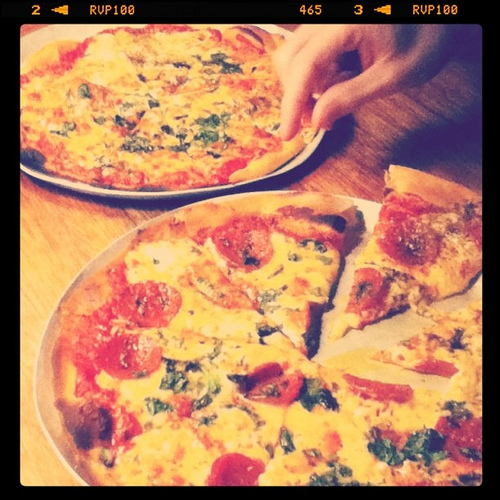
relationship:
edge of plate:
[21, 157, 143, 202] [11, 100, 330, 206]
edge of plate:
[22, 179, 251, 200] [16, 26, 333, 196]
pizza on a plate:
[24, 26, 321, 192] [11, 132, 365, 199]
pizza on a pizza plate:
[35, 160, 491, 500] [27, 178, 482, 486]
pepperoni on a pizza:
[390, 217, 438, 266] [335, 160, 495, 347]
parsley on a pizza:
[302, 375, 337, 407] [35, 160, 491, 500]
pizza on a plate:
[24, 26, 321, 192] [16, 26, 333, 196]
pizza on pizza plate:
[35, 160, 491, 500] [27, 178, 482, 486]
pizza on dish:
[17, 24, 317, 178] [23, 22, 344, 200]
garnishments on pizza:
[138, 353, 426, 424] [35, 160, 491, 500]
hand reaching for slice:
[268, 25, 464, 145] [180, 187, 357, 351]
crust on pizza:
[18, 181, 472, 491] [35, 160, 491, 500]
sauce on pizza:
[85, 160, 233, 190] [24, 26, 321, 192]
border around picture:
[2, 2, 498, 496] [18, 20, 488, 486]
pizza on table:
[24, 26, 321, 192] [24, 22, 485, 495]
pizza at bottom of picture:
[35, 160, 491, 500] [18, 20, 488, 486]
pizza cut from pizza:
[38, 160, 483, 487] [35, 160, 491, 500]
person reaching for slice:
[263, 21, 457, 141] [180, 187, 357, 351]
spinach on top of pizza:
[145, 327, 451, 484] [35, 160, 491, 500]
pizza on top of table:
[35, 160, 491, 500] [24, 22, 485, 495]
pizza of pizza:
[38, 160, 483, 487] [35, 160, 491, 500]